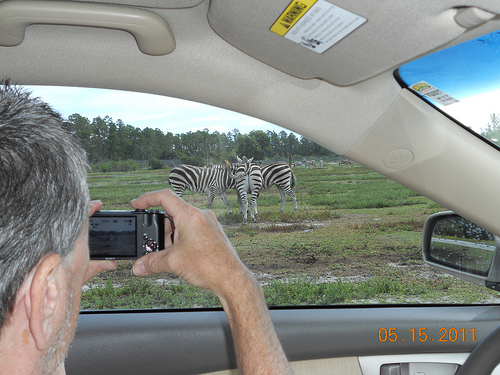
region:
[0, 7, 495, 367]
The man is taking a picture of zebras.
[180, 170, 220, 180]
The zebra has black and white stripes.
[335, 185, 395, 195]
The grass is green.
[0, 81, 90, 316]
The man has greyish brown hair.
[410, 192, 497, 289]
A mirror is attached to the car.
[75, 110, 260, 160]
Trees are in the distance.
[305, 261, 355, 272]
A patch of dirt on the ground.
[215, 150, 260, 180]
The zebra has a tail.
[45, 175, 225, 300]
A camera in the man's hand.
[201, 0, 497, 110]
A visor on the car.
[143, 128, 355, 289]
three zebras standing in a field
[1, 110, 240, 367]
man taking a picture of zebras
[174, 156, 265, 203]
black and white stripes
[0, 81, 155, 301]
dark and light grey hair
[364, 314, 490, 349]
orange printed date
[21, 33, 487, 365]
grey interior of a vehicle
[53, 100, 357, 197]
line of tall trees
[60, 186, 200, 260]
dark grey camera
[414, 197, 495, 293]
rear view mirror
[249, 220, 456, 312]
grass and puddles of water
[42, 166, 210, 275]
man taking a picture of zebras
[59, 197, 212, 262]
man is holding a camera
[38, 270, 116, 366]
man has a beard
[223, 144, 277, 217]
backside of the zebra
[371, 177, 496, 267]
left side mirror on car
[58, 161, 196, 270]
man is holding camera with two hands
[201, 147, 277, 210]
zebra's tail is swaying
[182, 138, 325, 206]
zebras are black and white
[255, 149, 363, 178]
animals behind the zebras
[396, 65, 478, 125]
sticker on the windshield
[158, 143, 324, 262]
a group of zebras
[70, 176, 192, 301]
small grey camera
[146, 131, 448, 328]
zebras standing in a field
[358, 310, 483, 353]
printed date in orange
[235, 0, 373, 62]
yellow and white warning label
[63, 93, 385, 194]
line of trees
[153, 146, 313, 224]
Three zebras standing in a field.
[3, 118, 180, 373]
Man taking picture of zebras.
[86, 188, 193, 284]
Camera in man's hands.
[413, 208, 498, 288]
Side view mirror on car.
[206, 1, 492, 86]
Partial view of sun visor in car.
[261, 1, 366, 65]
White and yellow warning label on sun visor.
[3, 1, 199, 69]
Hand support handle mounted on top side of car.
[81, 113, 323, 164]
Trees growing in distance beyond zebras.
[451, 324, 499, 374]
Small portion of car's steering wheel.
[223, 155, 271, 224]
Rear view of zebra swinging tail.